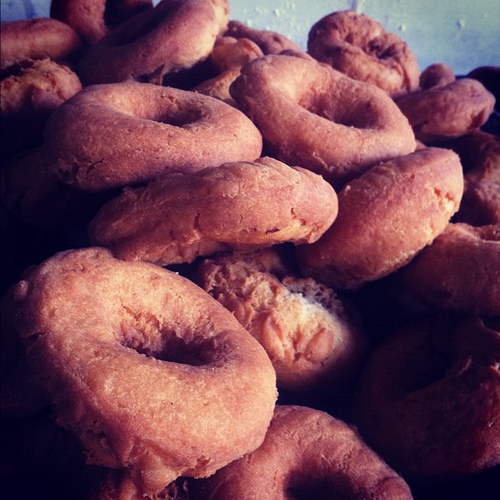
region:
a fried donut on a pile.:
[18, 241, 277, 489]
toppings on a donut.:
[247, 239, 357, 337]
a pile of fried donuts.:
[0, 1, 497, 493]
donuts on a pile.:
[232, 48, 417, 165]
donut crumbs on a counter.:
[252, 13, 298, 42]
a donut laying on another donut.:
[54, 81, 264, 189]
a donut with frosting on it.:
[201, 234, 353, 389]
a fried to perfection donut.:
[55, 79, 268, 188]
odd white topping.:
[289, 267, 357, 342]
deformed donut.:
[71, 402, 201, 498]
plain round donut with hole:
[65, 283, 260, 455]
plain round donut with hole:
[237, 412, 396, 497]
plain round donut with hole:
[209, 269, 332, 376]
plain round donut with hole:
[96, 92, 241, 167]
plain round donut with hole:
[261, 75, 390, 167]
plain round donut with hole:
[301, 12, 408, 86]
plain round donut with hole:
[432, 224, 499, 306]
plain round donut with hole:
[0, 21, 72, 53]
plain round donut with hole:
[83, 0, 143, 44]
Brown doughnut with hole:
[26, 253, 283, 465]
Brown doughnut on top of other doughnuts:
[55, 75, 267, 196]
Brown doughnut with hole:
[235, 44, 422, 177]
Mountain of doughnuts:
[1, 1, 498, 496]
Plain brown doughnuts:
[223, 397, 410, 498]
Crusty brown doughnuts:
[311, 6, 423, 102]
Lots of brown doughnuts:
[393, 74, 497, 124]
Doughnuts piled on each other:
[4, 5, 496, 494]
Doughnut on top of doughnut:
[63, 71, 342, 253]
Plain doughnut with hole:
[26, 234, 278, 464]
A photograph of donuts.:
[5, 5, 498, 497]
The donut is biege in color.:
[35, 240, 270, 471]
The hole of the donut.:
[101, 310, 213, 366]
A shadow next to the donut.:
[5, 390, 85, 495]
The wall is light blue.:
[415, 10, 490, 47]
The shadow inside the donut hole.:
[115, 85, 202, 130]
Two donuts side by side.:
[45, 260, 365, 495]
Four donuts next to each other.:
[67, 66, 457, 261]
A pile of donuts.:
[0, 0, 492, 497]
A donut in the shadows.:
[345, 313, 496, 463]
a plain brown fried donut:
[25, 248, 265, 465]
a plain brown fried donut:
[219, 398, 414, 495]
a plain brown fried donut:
[208, 256, 345, 381]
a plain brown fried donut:
[96, 159, 337, 261]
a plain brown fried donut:
[310, 148, 462, 277]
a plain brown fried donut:
[57, 83, 258, 173]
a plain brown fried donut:
[240, 47, 409, 169]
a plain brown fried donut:
[309, 8, 413, 98]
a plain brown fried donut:
[397, 71, 487, 141]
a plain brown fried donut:
[2, 58, 76, 115]